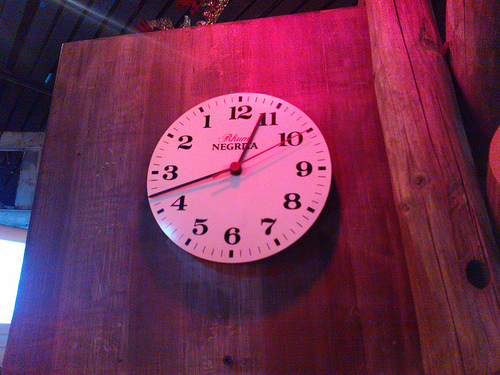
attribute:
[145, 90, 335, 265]
clock — hanging, white, black, large, reading, backwards, round, reversed, mounted, numbered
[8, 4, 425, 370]
wall — wooden, half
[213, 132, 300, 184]
hand — red, second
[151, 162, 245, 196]
hand — black, long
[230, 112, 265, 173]
hand — short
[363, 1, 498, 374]
post — wooden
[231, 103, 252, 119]
12 — black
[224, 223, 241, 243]
6 — black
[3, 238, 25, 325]
area — open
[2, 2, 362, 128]
ceiling — wooden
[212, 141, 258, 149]
writing — negrua, black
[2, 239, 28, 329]
light — pouring, shining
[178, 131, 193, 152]
2 — black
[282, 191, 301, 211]
8 — black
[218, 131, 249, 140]
lettering — red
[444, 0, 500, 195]
pole — brown